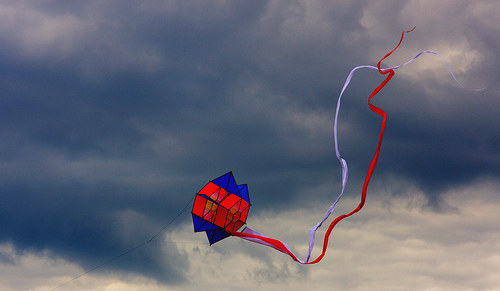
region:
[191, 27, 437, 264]
kite is red and blue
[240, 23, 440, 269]
kite has a long red and white tail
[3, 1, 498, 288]
sky is blue and cloudy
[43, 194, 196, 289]
kite has a long black string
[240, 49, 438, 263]
tail is long and purple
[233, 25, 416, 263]
tail is long and red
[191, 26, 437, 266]
kite is flying high in the air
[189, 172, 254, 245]
kite is diamond shaped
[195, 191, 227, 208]
kite has a small blue wing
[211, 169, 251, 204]
kite has triangle blue wings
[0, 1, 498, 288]
stormy sky is dark and cloudy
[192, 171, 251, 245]
kite box has blue tips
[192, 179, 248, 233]
middle of kite box is red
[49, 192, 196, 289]
kite string blends with the dark sky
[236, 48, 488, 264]
long kite tail is light purple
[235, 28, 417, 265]
long kite tail is bright red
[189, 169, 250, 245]
tips of kite box are pyramid shape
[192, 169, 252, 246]
kite box is made of two parallel sections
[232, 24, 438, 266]
purple and red tails are entwined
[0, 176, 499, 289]
lower portion of sky is lighter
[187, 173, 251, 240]
A red and blue kite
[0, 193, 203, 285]
A kite string in the air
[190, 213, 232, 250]
Blue material on a kite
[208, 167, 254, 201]
A blue piece of material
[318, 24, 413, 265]
A red string on a kite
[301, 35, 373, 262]
A lavender colored ribbon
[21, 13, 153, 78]
White cloud in a sky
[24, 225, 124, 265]
A section of blue sky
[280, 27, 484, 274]
Crossed colored ribbons on a kite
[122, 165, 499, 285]
White cloud bank in the sky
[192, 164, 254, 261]
red and blue kite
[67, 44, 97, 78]
white clouds in blue sky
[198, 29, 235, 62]
white clouds in blue sky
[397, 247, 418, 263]
white clouds in blue sky